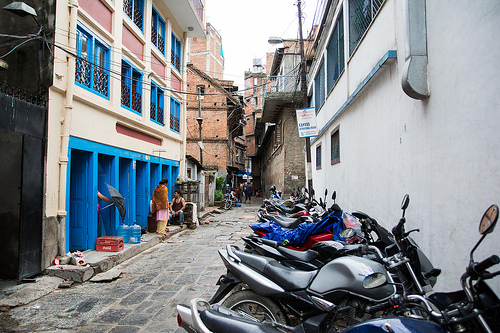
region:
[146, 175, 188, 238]
People speaking by the street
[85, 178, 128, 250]
Someone opening an umbrella from their door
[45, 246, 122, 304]
Cracked and dilapidated sidewalk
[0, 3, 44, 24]
A wall mounted street light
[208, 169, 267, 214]
People down the street mingling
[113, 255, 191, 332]
Stone built road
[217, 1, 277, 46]
A bright blue sky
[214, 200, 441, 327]
A line of motorcycles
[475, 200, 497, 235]
A motorcycle mirror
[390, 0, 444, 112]
A metal airvent on a wall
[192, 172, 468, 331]
several motorcycles parked in a row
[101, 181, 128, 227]
a person holding a umbrella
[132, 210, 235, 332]
a rock alley way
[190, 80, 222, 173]
a red brick building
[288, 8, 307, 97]
a wood electrical pole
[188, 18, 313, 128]
electrical wires hanging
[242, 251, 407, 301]
a grey motorcycle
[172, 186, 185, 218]
a man sitting down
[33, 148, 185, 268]
a building with blue doors and trim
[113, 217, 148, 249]
two large water bottles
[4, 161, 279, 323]
gray stone road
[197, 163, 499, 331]
a line of motor cycles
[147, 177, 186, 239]
a group of people on a walk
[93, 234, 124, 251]
a red and white boxes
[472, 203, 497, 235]
a round mirror on a cycle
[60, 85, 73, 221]
a cream colored pipe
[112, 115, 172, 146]
a opening in a wall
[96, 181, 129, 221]
a open umbrella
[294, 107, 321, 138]
a blue and white sign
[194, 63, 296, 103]
a bunch of electrie wires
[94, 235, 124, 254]
red crates on the ground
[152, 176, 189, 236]
people on the sidewalk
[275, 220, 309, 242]
blue cloth draped on motorcycle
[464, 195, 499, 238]
mirror on the motorcycle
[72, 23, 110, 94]
blue windows on the building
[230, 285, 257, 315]
tire on the motorcycle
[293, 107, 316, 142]
sign on the pole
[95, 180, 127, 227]
person with black umbrella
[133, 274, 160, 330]
cobblestone road with white lines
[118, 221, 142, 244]
water bottles on the sidewalk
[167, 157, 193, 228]
a man sitting outside a house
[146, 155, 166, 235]
a woman standing outside a house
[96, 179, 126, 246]
a lady holding an umbrella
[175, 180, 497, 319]
bikes parked in front of a wall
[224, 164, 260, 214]
people roaming on the street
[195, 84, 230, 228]
a lamp post by the side of the street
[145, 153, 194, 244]
people discussing outside a house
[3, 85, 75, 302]
a closed black color gate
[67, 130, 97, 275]
blue color door of a home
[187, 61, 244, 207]
a building without paint